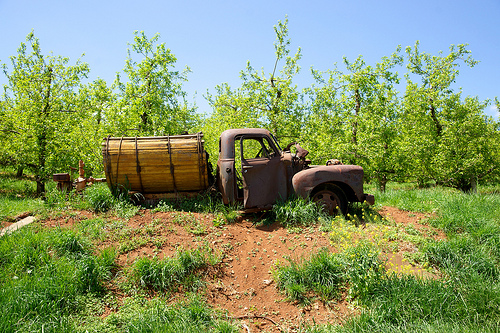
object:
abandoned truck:
[101, 128, 374, 219]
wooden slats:
[100, 135, 212, 197]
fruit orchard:
[0, 26, 202, 173]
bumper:
[365, 194, 375, 206]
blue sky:
[0, 0, 499, 82]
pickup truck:
[98, 126, 374, 225]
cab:
[215, 127, 311, 213]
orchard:
[19, 40, 468, 130]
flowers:
[331, 220, 397, 258]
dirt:
[154, 221, 292, 304]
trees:
[4, 41, 484, 141]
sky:
[11, 6, 484, 45]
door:
[229, 132, 283, 213]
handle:
[243, 164, 253, 171]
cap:
[226, 167, 231, 172]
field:
[0, 2, 500, 333]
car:
[100, 127, 376, 222]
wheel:
[310, 183, 354, 218]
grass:
[22, 222, 77, 327]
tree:
[403, 37, 485, 179]